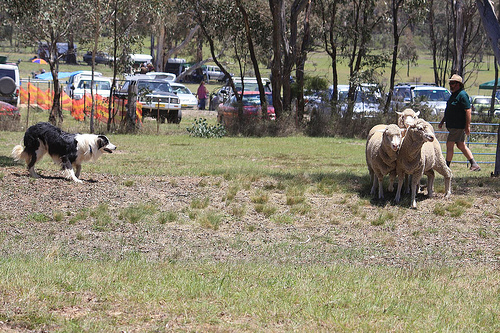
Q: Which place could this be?
A: It is a field.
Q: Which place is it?
A: It is a field.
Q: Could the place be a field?
A: Yes, it is a field.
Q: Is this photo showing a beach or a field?
A: It is showing a field.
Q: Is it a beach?
A: No, it is a field.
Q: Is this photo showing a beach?
A: No, the picture is showing a field.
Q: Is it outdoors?
A: Yes, it is outdoors.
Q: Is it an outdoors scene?
A: Yes, it is outdoors.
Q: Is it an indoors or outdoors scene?
A: It is outdoors.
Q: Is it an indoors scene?
A: No, it is outdoors.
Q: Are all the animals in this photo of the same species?
A: No, they are sheep and dogs.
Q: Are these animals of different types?
A: Yes, they are sheep and dogs.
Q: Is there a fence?
A: Yes, there is a fence.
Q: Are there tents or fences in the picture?
A: Yes, there is a fence.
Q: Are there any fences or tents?
A: Yes, there is a fence.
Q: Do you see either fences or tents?
A: Yes, there is a fence.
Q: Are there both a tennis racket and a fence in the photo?
A: No, there is a fence but no rackets.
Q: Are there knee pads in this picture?
A: No, there are no knee pads.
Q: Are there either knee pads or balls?
A: No, there are no knee pads or balls.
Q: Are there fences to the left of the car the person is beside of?
A: Yes, there is a fence to the left of the car.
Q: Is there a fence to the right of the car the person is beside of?
A: No, the fence is to the left of the car.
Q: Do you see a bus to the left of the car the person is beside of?
A: No, there is a fence to the left of the car.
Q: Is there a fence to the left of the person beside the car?
A: Yes, there is a fence to the left of the person.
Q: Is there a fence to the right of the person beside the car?
A: No, the fence is to the left of the person.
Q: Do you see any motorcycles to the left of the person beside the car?
A: No, there is a fence to the left of the person.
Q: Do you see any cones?
A: No, there are no cones.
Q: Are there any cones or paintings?
A: No, there are no cones or paintings.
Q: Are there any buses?
A: No, there are no buses.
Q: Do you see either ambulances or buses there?
A: No, there are no buses or ambulances.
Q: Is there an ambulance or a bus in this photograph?
A: No, there are no buses or ambulances.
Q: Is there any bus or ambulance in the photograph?
A: No, there are no buses or ambulances.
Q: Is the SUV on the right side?
A: No, the SUV is on the left of the image.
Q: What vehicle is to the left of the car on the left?
A: The vehicle is a SUV.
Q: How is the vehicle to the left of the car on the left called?
A: The vehicle is a SUV.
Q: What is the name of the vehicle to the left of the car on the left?
A: The vehicle is a SUV.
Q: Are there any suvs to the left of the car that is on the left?
A: Yes, there is a SUV to the left of the car.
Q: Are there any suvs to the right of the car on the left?
A: No, the SUV is to the left of the car.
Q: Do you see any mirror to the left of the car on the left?
A: No, there is a SUV to the left of the car.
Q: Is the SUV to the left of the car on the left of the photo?
A: Yes, the SUV is to the left of the car.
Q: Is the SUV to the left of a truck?
A: No, the SUV is to the left of the car.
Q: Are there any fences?
A: Yes, there is a fence.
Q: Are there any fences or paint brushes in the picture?
A: Yes, there is a fence.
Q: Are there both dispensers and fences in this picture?
A: No, there is a fence but no dispensers.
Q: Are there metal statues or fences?
A: Yes, there is a metal fence.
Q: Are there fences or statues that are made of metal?
A: Yes, the fence is made of metal.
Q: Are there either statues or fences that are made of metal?
A: Yes, the fence is made of metal.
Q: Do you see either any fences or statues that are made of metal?
A: Yes, the fence is made of metal.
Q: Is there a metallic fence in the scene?
A: Yes, there is a metal fence.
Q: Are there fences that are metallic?
A: Yes, there is a fence that is metallic.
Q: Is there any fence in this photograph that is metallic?
A: Yes, there is a fence that is metallic.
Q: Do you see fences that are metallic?
A: Yes, there is a fence that is metallic.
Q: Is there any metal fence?
A: Yes, there is a fence that is made of metal.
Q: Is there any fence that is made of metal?
A: Yes, there is a fence that is made of metal.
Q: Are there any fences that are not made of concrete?
A: Yes, there is a fence that is made of metal.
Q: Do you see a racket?
A: No, there are no rackets.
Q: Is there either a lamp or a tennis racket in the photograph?
A: No, there are no rackets or lamps.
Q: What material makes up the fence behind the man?
A: The fence is made of metal.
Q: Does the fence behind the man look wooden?
A: No, the fence is metallic.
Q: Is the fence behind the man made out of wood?
A: No, the fence is made of metal.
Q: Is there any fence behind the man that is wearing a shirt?
A: Yes, there is a fence behind the man.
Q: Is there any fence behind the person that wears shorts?
A: Yes, there is a fence behind the man.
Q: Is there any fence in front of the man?
A: No, the fence is behind the man.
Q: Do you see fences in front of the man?
A: No, the fence is behind the man.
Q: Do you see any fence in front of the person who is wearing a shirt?
A: No, the fence is behind the man.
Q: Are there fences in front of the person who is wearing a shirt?
A: No, the fence is behind the man.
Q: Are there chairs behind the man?
A: No, there is a fence behind the man.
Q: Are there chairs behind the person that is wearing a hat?
A: No, there is a fence behind the man.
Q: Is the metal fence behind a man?
A: Yes, the fence is behind a man.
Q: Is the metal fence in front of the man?
A: No, the fence is behind the man.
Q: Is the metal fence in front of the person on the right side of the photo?
A: No, the fence is behind the man.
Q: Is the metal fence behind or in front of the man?
A: The fence is behind the man.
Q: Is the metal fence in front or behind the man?
A: The fence is behind the man.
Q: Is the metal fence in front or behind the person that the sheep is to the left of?
A: The fence is behind the man.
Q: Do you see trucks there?
A: No, there are no trucks.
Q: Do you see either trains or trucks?
A: No, there are no trucks or trains.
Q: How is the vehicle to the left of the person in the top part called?
A: The vehicle is a car.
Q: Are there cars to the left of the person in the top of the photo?
A: Yes, there is a car to the left of the person.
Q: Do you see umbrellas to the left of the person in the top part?
A: No, there is a car to the left of the person.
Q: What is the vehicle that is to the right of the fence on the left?
A: The vehicle is a car.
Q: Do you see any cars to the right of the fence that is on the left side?
A: Yes, there is a car to the right of the fence.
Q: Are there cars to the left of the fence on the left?
A: No, the car is to the right of the fence.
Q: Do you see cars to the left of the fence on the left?
A: No, the car is to the right of the fence.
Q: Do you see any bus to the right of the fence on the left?
A: No, there is a car to the right of the fence.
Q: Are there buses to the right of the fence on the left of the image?
A: No, there is a car to the right of the fence.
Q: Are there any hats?
A: Yes, there is a hat.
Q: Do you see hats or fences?
A: Yes, there is a hat.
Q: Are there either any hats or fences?
A: Yes, there is a hat.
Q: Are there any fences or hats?
A: Yes, there is a hat.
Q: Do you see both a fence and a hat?
A: Yes, there are both a hat and a fence.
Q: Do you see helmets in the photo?
A: No, there are no helmets.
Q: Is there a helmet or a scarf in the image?
A: No, there are no helmets or scarves.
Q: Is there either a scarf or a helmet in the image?
A: No, there are no helmets or scarves.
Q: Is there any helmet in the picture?
A: No, there are no helmets.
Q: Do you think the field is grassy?
A: Yes, the field is grassy.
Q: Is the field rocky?
A: No, the field is grassy.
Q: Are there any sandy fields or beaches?
A: No, there is a field but it is grassy.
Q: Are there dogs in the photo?
A: Yes, there is a dog.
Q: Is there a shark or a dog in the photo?
A: Yes, there is a dog.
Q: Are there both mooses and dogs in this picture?
A: No, there is a dog but no mooses.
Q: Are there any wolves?
A: No, there are no wolves.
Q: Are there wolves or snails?
A: No, there are no wolves or snails.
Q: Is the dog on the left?
A: Yes, the dog is on the left of the image.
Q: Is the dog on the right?
A: No, the dog is on the left of the image.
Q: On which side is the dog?
A: The dog is on the left of the image.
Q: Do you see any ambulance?
A: No, there are no ambulances.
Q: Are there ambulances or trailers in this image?
A: No, there are no ambulances or trailers.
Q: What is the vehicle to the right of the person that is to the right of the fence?
A: The vehicle is a car.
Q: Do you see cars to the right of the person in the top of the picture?
A: Yes, there is a car to the right of the person.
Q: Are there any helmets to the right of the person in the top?
A: No, there is a car to the right of the person.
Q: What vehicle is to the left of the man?
A: The vehicle is a car.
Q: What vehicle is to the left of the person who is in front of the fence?
A: The vehicle is a car.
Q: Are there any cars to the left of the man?
A: Yes, there is a car to the left of the man.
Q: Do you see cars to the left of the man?
A: Yes, there is a car to the left of the man.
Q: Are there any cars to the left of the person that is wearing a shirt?
A: Yes, there is a car to the left of the man.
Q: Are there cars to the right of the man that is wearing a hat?
A: No, the car is to the left of the man.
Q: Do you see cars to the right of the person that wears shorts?
A: No, the car is to the left of the man.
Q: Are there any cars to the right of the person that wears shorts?
A: No, the car is to the left of the man.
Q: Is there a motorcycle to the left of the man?
A: No, there is a car to the left of the man.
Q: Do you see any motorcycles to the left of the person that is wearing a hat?
A: No, there is a car to the left of the man.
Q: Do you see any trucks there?
A: No, there are no trucks.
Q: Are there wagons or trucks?
A: No, there are no trucks or wagons.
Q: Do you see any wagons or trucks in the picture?
A: No, there are no trucks or wagons.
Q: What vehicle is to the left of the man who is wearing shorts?
A: The vehicle is a car.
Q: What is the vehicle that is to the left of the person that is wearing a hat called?
A: The vehicle is a car.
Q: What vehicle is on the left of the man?
A: The vehicle is a car.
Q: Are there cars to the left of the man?
A: Yes, there is a car to the left of the man.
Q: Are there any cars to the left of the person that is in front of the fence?
A: Yes, there is a car to the left of the man.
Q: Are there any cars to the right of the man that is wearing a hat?
A: No, the car is to the left of the man.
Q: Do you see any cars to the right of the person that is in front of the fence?
A: No, the car is to the left of the man.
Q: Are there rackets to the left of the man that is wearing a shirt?
A: No, there is a car to the left of the man.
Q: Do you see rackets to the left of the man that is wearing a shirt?
A: No, there is a car to the left of the man.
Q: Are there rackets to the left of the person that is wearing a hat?
A: No, there is a car to the left of the man.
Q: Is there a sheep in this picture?
A: Yes, there is a sheep.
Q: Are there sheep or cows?
A: Yes, there is a sheep.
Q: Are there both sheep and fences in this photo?
A: Yes, there are both a sheep and a fence.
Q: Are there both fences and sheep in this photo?
A: Yes, there are both a sheep and a fence.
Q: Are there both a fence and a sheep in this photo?
A: Yes, there are both a sheep and a fence.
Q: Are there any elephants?
A: No, there are no elephants.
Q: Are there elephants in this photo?
A: No, there are no elephants.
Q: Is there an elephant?
A: No, there are no elephants.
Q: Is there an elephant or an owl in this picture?
A: No, there are no elephants or owls.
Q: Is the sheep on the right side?
A: Yes, the sheep is on the right of the image.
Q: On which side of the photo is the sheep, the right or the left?
A: The sheep is on the right of the image.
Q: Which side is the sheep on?
A: The sheep is on the right of the image.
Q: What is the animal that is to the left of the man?
A: The animal is a sheep.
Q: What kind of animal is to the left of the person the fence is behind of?
A: The animal is a sheep.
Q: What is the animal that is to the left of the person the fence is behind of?
A: The animal is a sheep.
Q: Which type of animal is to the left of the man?
A: The animal is a sheep.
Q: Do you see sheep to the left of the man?
A: Yes, there is a sheep to the left of the man.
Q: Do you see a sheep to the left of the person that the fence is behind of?
A: Yes, there is a sheep to the left of the man.